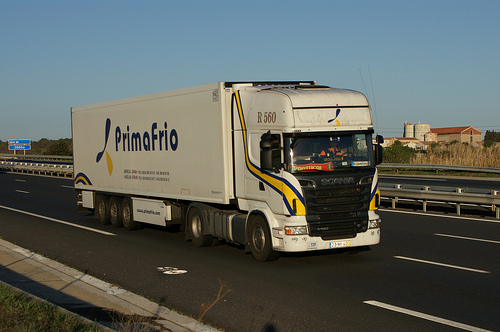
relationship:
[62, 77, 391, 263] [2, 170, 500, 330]
truck on road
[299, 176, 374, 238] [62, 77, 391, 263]
grill on truck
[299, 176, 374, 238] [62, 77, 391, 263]
grill on front of truck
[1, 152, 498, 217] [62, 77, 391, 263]
fence besides truck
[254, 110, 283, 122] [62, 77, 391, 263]
number on truck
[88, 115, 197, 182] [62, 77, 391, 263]
logo on truck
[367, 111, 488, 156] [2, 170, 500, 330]
building besides road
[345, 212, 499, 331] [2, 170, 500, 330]
lines on road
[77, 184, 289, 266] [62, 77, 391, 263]
wheels on truck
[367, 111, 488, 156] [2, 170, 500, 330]
building near road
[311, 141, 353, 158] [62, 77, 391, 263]
person inside truck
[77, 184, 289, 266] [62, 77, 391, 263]
wheels under truck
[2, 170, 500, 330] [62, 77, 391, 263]
road under truck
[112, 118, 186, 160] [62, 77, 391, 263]
writing on truck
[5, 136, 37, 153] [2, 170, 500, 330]
sign near road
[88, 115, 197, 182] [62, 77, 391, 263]
logo on side of truck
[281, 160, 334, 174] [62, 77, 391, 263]
tag on truck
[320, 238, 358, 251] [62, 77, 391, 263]
plate on truck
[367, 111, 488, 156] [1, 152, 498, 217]
building behind fence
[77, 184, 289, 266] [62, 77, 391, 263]
wheels underneath truck